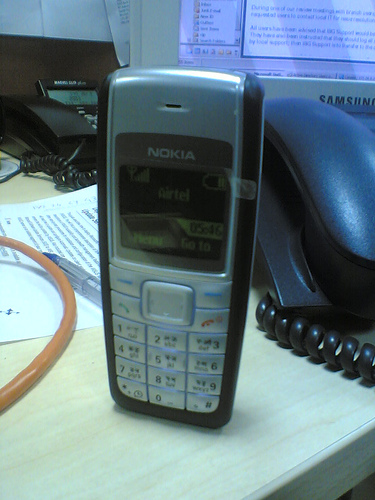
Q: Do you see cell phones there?
A: Yes, there is a cell phone.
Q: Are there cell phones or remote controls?
A: Yes, there is a cell phone.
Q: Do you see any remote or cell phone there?
A: Yes, there is a cell phone.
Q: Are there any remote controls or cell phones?
A: Yes, there is a cell phone.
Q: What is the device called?
A: The device is a cell phone.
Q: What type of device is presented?
A: The device is a cell phone.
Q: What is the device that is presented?
A: The device is a cell phone.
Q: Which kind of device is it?
A: The device is a cell phone.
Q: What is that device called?
A: That is a cell phone.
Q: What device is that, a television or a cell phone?
A: That is a cell phone.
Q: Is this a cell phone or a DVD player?
A: This is a cell phone.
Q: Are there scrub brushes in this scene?
A: No, there are no scrub brushes.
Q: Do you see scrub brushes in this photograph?
A: No, there are no scrub brushes.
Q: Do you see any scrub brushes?
A: No, there are no scrub brushes.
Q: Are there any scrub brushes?
A: No, there are no scrub brushes.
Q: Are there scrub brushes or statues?
A: No, there are no scrub brushes or statues.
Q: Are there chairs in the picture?
A: No, there are no chairs.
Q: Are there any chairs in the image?
A: No, there are no chairs.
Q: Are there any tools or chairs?
A: No, there are no chairs or tools.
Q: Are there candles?
A: No, there are no candles.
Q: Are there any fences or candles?
A: No, there are no candles or fences.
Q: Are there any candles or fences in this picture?
A: No, there are no candles or fences.